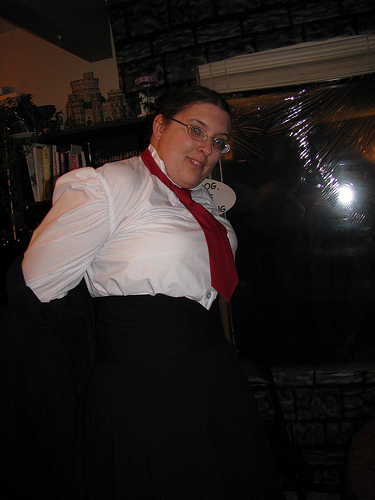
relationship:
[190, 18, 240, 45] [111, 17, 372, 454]
brick on wall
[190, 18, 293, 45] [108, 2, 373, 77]
brick on wall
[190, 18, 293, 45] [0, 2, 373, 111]
brick on wall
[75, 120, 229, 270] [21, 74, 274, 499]
shirt on lady